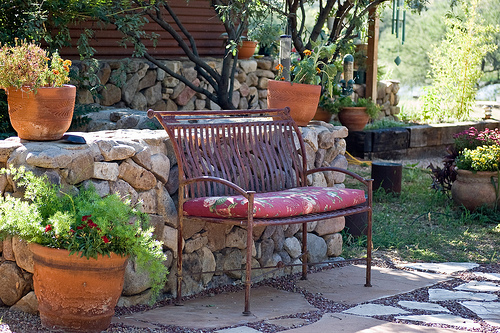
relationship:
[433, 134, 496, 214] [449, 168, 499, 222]
plant in planter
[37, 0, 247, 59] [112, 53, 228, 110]
brown siding above wall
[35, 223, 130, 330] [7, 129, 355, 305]
planter in front of wall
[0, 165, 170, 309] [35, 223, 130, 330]
flowering in planter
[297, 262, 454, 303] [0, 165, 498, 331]
flat stone on ground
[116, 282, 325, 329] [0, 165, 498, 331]
flat stone on ground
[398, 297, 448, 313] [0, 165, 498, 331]
flat stone on ground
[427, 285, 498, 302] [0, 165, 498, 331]
flat stone on ground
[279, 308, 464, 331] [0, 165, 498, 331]
flat stone on ground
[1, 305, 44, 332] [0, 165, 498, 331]
small stones on ground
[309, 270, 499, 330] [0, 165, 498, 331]
small stones on ground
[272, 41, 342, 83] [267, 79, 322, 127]
greenery in feeders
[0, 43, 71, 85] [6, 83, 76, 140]
greenery in flowerpot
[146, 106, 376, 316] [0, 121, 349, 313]
bench in front of fence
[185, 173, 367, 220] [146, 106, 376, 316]
cushion on bench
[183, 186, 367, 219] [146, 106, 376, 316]
cushion on bench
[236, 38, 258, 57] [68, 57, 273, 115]
flower pot on rock wall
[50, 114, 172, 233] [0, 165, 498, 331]
gravel on ground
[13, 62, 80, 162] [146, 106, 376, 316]
flowerpot beside bench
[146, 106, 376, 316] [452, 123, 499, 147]
bench beside flowers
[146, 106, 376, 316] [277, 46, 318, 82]
bench beside flowers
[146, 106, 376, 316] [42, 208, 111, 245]
bench beside flowers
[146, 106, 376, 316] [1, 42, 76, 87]
bench beside flowers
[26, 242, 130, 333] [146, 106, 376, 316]
planter by bench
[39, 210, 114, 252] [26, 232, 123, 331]
flowers in pot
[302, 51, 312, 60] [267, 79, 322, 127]
flower in feeders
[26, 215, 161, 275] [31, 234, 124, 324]
flower in pot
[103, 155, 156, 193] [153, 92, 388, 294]
stone by bench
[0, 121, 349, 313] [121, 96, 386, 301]
fence behind bench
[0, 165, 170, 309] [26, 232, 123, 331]
flowering in pot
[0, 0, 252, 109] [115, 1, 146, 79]
tree with leaves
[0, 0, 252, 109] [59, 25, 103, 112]
tree with leaves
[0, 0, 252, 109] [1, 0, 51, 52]
tree with leaves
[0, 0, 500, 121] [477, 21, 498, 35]
tree with leaves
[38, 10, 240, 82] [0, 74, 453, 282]
wall behind fence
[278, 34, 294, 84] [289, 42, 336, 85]
birdfeeder by plant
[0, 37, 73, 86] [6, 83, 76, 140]
flowers in flowerpot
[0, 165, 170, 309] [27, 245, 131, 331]
flowering in pot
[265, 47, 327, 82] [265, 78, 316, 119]
plant in pot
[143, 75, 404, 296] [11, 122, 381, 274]
bench by wall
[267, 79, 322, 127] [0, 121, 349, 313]
feeders on fence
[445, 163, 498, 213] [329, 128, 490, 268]
planter on grass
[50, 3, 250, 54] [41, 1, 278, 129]
brown siding on house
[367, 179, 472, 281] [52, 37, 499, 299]
grass in yard